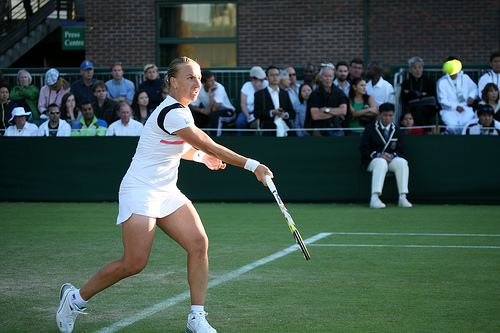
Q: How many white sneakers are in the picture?
A: Four.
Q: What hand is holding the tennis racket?
A: Right.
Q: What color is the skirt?
A: White.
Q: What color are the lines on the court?
A: White.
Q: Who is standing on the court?
A: The tennis player.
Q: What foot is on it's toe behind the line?
A: Right foot.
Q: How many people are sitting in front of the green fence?
A: One.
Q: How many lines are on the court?
A: Three.